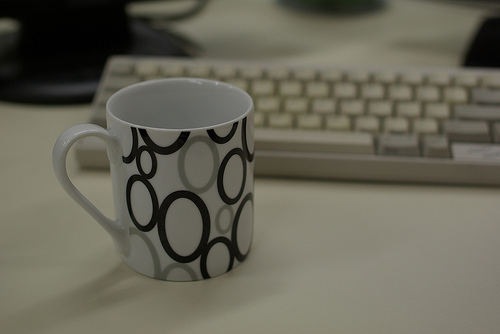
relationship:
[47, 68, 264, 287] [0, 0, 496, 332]
mug on table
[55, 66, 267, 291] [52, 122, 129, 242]
cup has handle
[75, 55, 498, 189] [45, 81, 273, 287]
keyboard near cup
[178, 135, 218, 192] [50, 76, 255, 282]
circle on mug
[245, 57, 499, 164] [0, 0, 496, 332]
keyboard on table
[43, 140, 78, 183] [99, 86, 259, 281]
handle of cup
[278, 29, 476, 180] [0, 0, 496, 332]
keyboard on table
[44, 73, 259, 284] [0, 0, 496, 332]
cup on table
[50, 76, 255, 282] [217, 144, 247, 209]
mug with circle art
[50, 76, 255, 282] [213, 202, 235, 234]
mug with circle art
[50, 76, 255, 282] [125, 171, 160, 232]
mug with circle art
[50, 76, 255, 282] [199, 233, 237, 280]
mug with circle art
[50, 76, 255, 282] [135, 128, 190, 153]
mug with circle art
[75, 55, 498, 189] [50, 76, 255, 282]
keyboard behind mug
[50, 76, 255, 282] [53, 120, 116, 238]
mug has handle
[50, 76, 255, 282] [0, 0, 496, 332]
mug on table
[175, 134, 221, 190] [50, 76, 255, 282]
grey circle on mug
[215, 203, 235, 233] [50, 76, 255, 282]
grey circle on mug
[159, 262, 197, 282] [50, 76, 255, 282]
grey circle on mug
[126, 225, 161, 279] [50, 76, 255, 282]
grey circle on mug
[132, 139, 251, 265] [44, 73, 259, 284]
circles on cup